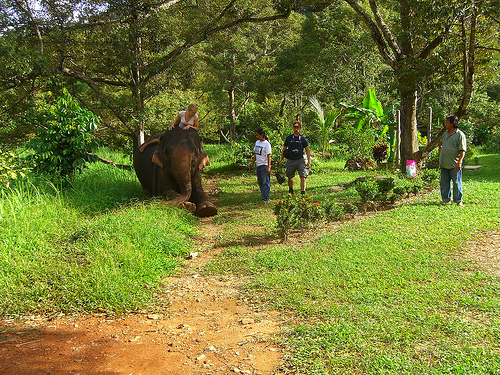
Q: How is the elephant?
A: Kneeling towards the ground.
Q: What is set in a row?
A: Flowering plants.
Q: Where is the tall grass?
A: Near the elephant.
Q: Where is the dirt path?
A: It is through the grass.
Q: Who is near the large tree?
A: The man.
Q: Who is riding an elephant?
A: A woman.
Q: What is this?
A: A narrow walking trail.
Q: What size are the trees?
A: They are of all sizes.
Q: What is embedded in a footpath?
A: Rocks.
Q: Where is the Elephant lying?
A: On grass.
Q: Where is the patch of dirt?
A: Bottom left corner.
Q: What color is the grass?
A: Green.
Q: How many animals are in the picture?
A: One.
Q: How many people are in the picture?
A: Four.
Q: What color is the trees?
A: Green.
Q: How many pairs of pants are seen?
A: Two.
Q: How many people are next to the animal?
A: Two.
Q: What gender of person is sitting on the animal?
A: Female.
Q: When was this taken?
A: During the day.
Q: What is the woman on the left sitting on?
A: An elephant.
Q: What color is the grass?
A: Green.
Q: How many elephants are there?
A: One.